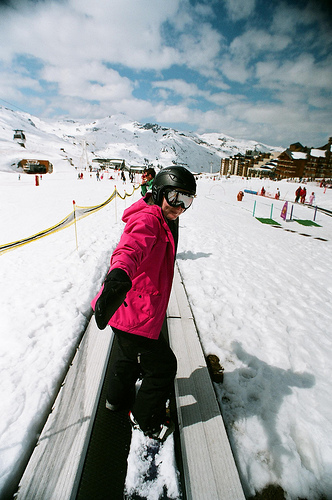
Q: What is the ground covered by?
A: The ground is covered by the snow.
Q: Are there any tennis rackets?
A: No, there are no tennis rackets.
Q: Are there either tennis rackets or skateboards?
A: No, there are no tennis rackets or skateboards.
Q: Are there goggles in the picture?
A: Yes, there are goggles.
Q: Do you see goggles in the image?
A: Yes, there are goggles.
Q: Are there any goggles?
A: Yes, there are goggles.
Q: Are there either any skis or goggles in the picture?
A: Yes, there are goggles.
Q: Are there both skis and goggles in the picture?
A: No, there are goggles but no skis.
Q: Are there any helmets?
A: Yes, there is a helmet.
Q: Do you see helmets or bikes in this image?
A: Yes, there is a helmet.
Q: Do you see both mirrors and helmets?
A: No, there is a helmet but no mirrors.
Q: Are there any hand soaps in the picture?
A: No, there are no hand soaps.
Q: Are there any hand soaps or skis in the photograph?
A: No, there are no hand soaps or skis.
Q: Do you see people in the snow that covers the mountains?
A: Yes, there are people in the snow.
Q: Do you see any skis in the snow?
A: No, there are people in the snow.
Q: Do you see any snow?
A: Yes, there is snow.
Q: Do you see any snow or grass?
A: Yes, there is snow.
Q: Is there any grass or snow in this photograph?
A: Yes, there is snow.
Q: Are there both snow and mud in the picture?
A: No, there is snow but no mud.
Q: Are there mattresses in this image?
A: No, there are no mattresses.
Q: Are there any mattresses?
A: No, there are no mattresses.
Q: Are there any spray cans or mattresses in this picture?
A: No, there are no mattresses or spray cans.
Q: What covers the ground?
A: The snow covers the ground.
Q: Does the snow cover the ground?
A: Yes, the snow covers the ground.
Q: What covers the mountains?
A: The snow covers the mountains.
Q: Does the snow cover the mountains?
A: Yes, the snow covers the mountains.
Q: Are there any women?
A: Yes, there is a woman.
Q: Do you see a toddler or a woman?
A: Yes, there is a woman.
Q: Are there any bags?
A: No, there are no bags.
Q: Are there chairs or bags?
A: No, there are no bags or chairs.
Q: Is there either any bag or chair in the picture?
A: No, there are no bags or chairs.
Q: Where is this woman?
A: The woman is in the snow.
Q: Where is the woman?
A: The woman is in the snow.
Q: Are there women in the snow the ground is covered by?
A: Yes, there is a woman in the snow.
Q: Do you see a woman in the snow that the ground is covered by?
A: Yes, there is a woman in the snow.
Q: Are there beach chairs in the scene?
A: No, there are no beach chairs.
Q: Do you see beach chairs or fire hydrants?
A: No, there are no beach chairs or fire hydrants.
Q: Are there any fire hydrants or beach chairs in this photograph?
A: No, there are no beach chairs or fire hydrants.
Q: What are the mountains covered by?
A: The mountains are covered by the snow.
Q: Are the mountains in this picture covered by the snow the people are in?
A: Yes, the mountains are covered by the snow.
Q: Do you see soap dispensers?
A: No, there are no soap dispensers.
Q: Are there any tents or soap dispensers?
A: No, there are no soap dispensers or tents.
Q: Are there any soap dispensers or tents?
A: No, there are no soap dispensers or tents.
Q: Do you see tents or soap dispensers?
A: No, there are no soap dispensers or tents.